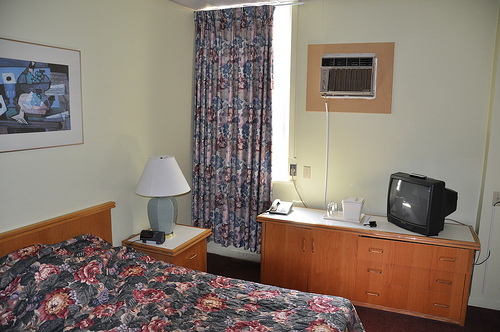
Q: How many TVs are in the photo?
A: One.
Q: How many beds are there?
A: One.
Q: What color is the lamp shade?
A: White.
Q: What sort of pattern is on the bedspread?
A: Floral.